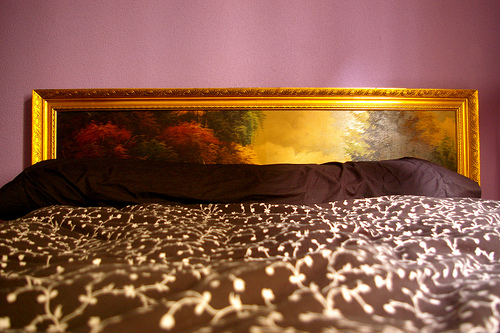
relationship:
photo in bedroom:
[80, 68, 161, 150] [298, 35, 459, 285]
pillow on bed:
[63, 160, 411, 198] [62, 168, 223, 271]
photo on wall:
[80, 68, 161, 150] [139, 23, 191, 45]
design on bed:
[168, 249, 196, 277] [62, 168, 223, 271]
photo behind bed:
[80, 68, 161, 150] [62, 168, 223, 271]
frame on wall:
[204, 80, 246, 99] [139, 23, 191, 45]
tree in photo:
[136, 231, 171, 252] [80, 68, 161, 150]